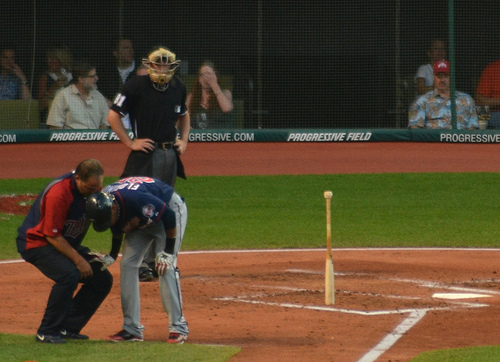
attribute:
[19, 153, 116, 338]
man — squatting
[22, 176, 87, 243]
shirt — red, blue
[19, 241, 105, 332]
pants — black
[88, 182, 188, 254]
baseball player — leaning over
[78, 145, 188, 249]
player — baseball, bent over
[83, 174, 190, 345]
player — in pain, leaning over, baseball, hunched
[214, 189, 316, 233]
grass — short, green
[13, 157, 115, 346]
trainer — baseball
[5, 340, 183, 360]
grass — short, green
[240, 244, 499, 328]
diamond — baseball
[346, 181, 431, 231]
grass — very, short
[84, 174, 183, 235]
shirt — blue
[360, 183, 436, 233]
grass — short, green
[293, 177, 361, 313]
bat — wooden, baseball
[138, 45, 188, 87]
helmet — gold, ump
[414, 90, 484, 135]
shirt — hawaiian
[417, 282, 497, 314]
homeplate — home, white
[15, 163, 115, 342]
man — bending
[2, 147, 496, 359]
field — baseball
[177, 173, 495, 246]
grass — green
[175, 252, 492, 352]
dirt — brown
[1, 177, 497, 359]
field — baseball